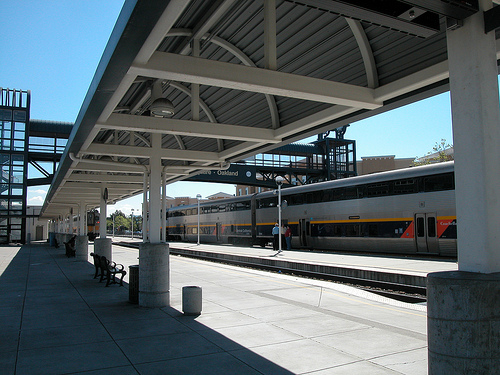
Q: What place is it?
A: It is a train station.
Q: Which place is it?
A: It is a train station.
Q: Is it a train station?
A: Yes, it is a train station.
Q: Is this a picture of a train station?
A: Yes, it is showing a train station.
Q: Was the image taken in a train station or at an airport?
A: It was taken at a train station.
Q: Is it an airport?
A: No, it is a train station.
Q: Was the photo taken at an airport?
A: No, the picture was taken in a train station.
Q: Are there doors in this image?
A: Yes, there are doors.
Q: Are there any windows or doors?
A: Yes, there are doors.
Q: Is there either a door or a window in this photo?
A: Yes, there are doors.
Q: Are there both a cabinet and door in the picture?
A: No, there are doors but no cabinets.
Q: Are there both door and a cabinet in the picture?
A: No, there are doors but no cabinets.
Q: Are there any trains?
A: Yes, there is a train.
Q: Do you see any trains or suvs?
A: Yes, there is a train.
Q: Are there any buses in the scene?
A: No, there are no buses.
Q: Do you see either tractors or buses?
A: No, there are no buses or tractors.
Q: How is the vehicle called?
A: The vehicle is a train.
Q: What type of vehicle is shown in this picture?
A: The vehicle is a train.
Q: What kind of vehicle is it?
A: The vehicle is a train.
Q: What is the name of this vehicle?
A: This is a train.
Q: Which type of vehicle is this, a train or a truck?
A: This is a train.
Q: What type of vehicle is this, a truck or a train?
A: This is a train.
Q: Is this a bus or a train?
A: This is a train.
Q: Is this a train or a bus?
A: This is a train.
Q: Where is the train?
A: The train is at the train station.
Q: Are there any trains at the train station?
A: Yes, there is a train at the train station.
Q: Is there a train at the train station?
A: Yes, there is a train at the train station.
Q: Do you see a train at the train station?
A: Yes, there is a train at the train station.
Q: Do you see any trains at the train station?
A: Yes, there is a train at the train station.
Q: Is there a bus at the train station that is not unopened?
A: No, there is a train at the train station.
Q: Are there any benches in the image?
A: Yes, there is a bench.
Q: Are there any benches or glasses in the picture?
A: Yes, there is a bench.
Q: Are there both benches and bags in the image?
A: No, there is a bench but no bags.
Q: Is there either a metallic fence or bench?
A: Yes, there is a metal bench.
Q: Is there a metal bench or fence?
A: Yes, there is a metal bench.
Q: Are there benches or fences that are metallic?
A: Yes, the bench is metallic.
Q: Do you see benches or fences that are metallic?
A: Yes, the bench is metallic.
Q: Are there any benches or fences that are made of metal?
A: Yes, the bench is made of metal.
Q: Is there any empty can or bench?
A: Yes, there is an empty bench.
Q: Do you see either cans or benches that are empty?
A: Yes, the bench is empty.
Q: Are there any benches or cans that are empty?
A: Yes, the bench is empty.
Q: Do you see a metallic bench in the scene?
A: Yes, there is a metal bench.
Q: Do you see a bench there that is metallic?
A: Yes, there is a bench that is metallic.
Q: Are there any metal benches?
A: Yes, there is a bench that is made of metal.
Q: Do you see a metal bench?
A: Yes, there is a bench that is made of metal.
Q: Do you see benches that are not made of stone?
A: Yes, there is a bench that is made of metal.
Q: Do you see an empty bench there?
A: Yes, there is an empty bench.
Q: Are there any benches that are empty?
A: Yes, there is a bench that is empty.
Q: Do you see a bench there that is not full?
A: Yes, there is a empty bench.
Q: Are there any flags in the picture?
A: No, there are no flags.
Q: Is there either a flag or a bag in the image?
A: No, there are no flags or bags.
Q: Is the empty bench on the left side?
A: Yes, the bench is on the left of the image.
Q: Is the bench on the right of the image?
A: No, the bench is on the left of the image.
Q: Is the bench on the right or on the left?
A: The bench is on the left of the image.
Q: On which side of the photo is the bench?
A: The bench is on the left of the image.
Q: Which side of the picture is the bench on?
A: The bench is on the left of the image.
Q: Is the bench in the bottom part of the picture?
A: Yes, the bench is in the bottom of the image.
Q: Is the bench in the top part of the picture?
A: No, the bench is in the bottom of the image.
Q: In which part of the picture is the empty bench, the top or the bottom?
A: The bench is in the bottom of the image.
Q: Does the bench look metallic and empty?
A: Yes, the bench is metallic and empty.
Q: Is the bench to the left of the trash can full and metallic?
A: No, the bench is metallic but empty.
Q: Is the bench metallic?
A: Yes, the bench is metallic.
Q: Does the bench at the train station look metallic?
A: Yes, the bench is metallic.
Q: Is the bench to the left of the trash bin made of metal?
A: Yes, the bench is made of metal.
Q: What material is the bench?
A: The bench is made of metal.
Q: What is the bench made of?
A: The bench is made of metal.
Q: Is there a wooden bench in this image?
A: No, there is a bench but it is metallic.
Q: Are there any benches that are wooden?
A: No, there is a bench but it is metallic.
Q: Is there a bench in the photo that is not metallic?
A: No, there is a bench but it is metallic.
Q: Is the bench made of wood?
A: No, the bench is made of metal.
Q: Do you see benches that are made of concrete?
A: No, there is a bench but it is made of metal.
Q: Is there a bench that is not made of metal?
A: No, there is a bench but it is made of metal.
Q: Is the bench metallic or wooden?
A: The bench is metallic.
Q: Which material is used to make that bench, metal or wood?
A: The bench is made of metal.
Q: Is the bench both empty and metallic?
A: Yes, the bench is empty and metallic.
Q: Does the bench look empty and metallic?
A: Yes, the bench is empty and metallic.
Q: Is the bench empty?
A: Yes, the bench is empty.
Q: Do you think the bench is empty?
A: Yes, the bench is empty.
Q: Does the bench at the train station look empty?
A: Yes, the bench is empty.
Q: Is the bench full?
A: No, the bench is empty.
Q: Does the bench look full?
A: No, the bench is empty.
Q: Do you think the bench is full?
A: No, the bench is empty.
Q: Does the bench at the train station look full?
A: No, the bench is empty.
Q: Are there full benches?
A: No, there is a bench but it is empty.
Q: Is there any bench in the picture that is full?
A: No, there is a bench but it is empty.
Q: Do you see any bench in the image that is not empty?
A: No, there is a bench but it is empty.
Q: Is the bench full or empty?
A: The bench is empty.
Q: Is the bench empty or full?
A: The bench is empty.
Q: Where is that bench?
A: The bench is at the train station.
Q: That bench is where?
A: The bench is at the train station.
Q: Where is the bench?
A: The bench is at the train station.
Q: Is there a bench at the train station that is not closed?
A: Yes, there is a bench at the train station.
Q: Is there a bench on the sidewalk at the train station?
A: Yes, there is a bench on the sidewalk.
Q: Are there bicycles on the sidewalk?
A: No, there is a bench on the sidewalk.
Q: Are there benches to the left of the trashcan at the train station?
A: Yes, there is a bench to the left of the trashcan.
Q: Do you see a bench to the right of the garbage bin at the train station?
A: No, the bench is to the left of the trash bin.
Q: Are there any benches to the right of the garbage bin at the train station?
A: No, the bench is to the left of the trash bin.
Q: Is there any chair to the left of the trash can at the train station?
A: No, there is a bench to the left of the trash can.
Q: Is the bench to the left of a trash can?
A: Yes, the bench is to the left of a trash can.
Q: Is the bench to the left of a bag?
A: No, the bench is to the left of a trash can.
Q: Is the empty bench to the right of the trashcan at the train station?
A: No, the bench is to the left of the trash bin.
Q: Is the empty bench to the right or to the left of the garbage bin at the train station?
A: The bench is to the left of the trashcan.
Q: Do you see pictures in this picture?
A: No, there are no pictures.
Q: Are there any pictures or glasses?
A: No, there are no pictures or glasses.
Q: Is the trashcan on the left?
A: Yes, the trashcan is on the left of the image.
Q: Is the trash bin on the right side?
A: No, the trash bin is on the left of the image.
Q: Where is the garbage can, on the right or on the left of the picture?
A: The garbage can is on the left of the image.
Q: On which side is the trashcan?
A: The trashcan is on the left of the image.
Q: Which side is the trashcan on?
A: The trashcan is on the left of the image.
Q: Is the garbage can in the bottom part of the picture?
A: Yes, the garbage can is in the bottom of the image.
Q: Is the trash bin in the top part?
A: No, the trash bin is in the bottom of the image.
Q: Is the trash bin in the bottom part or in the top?
A: The trash bin is in the bottom of the image.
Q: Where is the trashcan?
A: The trashcan is at the train station.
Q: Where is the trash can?
A: The trashcan is at the train station.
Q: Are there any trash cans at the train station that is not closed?
A: Yes, there is a trash can at the train station.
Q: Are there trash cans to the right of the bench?
A: Yes, there is a trash can to the right of the bench.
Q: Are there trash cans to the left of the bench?
A: No, the trash can is to the right of the bench.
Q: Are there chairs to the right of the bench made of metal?
A: No, there is a trash can to the right of the bench.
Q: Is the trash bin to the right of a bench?
A: Yes, the trash bin is to the right of a bench.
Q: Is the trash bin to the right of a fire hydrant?
A: No, the trash bin is to the right of a bench.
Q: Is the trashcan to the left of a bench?
A: No, the trashcan is to the right of a bench.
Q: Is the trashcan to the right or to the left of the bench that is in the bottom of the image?
A: The trashcan is to the right of the bench.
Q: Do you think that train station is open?
A: Yes, the train station is open.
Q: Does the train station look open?
A: Yes, the train station is open.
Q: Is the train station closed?
A: No, the train station is open.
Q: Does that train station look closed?
A: No, the train station is open.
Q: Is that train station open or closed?
A: The train station is open.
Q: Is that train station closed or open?
A: The train station is open.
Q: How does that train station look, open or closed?
A: The train station is open.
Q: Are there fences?
A: No, there are no fences.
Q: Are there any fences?
A: No, there are no fences.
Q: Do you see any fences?
A: No, there are no fences.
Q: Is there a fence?
A: No, there are no fences.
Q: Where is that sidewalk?
A: The sidewalk is at the train station.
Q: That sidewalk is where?
A: The sidewalk is at the train station.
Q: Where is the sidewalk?
A: The sidewalk is at the train station.